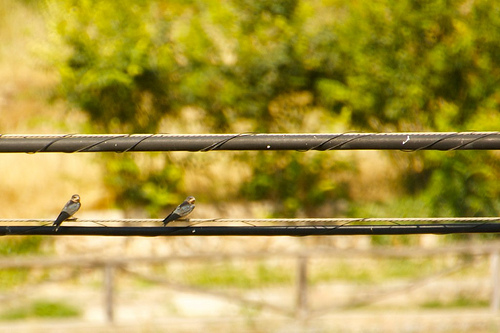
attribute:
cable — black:
[1, 222, 499, 237]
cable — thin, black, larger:
[0, 132, 500, 152]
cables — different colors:
[231, 116, 496, 163]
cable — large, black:
[3, 130, 498, 165]